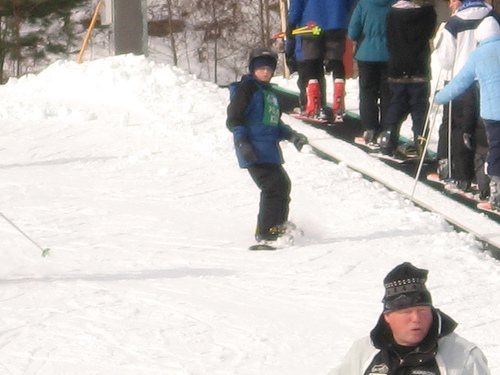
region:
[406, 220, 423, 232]
part of the snow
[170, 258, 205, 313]
edge of a hill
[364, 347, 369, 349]
part of a jacket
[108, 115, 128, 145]
tip of a hill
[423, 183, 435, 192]
part of a board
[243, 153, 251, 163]
part of a glove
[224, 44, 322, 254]
child dressed in black and blue on short skis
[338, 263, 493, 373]
man with black, gray and white knitted hat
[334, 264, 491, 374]
man wearing a black and white ski jacket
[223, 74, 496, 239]
short ski lift with six skiers riding up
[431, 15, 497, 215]
skier with white hat, blue jacket and black pants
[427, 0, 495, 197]
skier with black pants and black and white jacket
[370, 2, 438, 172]
skier with blue pants and black jacket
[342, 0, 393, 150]
skier with black pants and a blue jacket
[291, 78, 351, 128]
skier's feet in red ski boots on short skis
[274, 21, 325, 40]
yellow and red ski poles in black gloved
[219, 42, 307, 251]
a kid on a snowboard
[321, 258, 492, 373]
man in a black hat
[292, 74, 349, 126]
pair of red ski boots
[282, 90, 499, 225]
row of snowboards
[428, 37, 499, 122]
pastel blue jacket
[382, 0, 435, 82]
a black hoody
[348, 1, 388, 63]
a teal jacket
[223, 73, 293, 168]
a blue jacket with black sleeves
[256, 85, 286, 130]
green sign on the kid's chest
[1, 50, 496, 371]
a snowy hill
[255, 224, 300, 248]
A snowboard beneath the boy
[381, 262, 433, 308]
The man is wearing a hat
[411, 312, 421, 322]
The nose of the man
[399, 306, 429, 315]
The eyes of the man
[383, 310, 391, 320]
The ear of the man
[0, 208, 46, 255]
A ski pole above the snow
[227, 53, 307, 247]
A boy snowboarding on the snow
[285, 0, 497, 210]
People waiting in line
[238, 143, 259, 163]
The boy is wearing gloves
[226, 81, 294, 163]
The boy is wearing a jacket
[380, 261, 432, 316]
A warm black hat.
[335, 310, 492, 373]
A white jacket,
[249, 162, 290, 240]
Warm black pants.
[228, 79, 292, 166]
A heavy blue jacket.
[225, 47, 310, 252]
A little boy in white skates.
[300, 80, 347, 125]
Bright red skates.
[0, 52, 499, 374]
A hill covered in snow.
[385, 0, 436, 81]
A black jacket with a hood.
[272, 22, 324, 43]
A pair of ski poles.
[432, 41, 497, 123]
A light blue thick jacket.